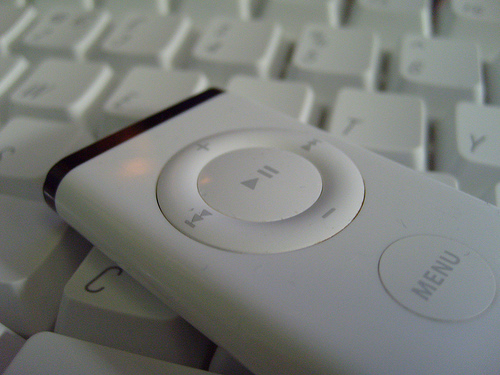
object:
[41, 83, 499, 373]
controler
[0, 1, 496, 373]
keyboard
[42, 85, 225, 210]
top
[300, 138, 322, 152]
arrow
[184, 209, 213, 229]
arrow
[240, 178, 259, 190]
arrow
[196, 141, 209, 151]
plus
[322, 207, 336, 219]
minus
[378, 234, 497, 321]
menu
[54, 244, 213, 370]
button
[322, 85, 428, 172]
key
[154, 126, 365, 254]
button